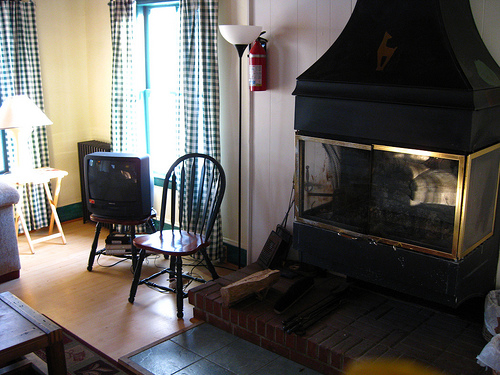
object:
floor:
[0, 216, 246, 363]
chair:
[127, 151, 226, 320]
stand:
[85, 209, 158, 272]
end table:
[0, 167, 68, 253]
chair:
[0, 186, 25, 284]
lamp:
[0, 94, 53, 182]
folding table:
[0, 167, 70, 255]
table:
[1, 290, 151, 374]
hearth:
[188, 230, 500, 374]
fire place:
[289, 0, 498, 321]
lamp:
[218, 25, 261, 267]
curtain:
[105, 2, 138, 155]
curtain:
[175, 4, 223, 263]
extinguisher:
[247, 30, 269, 91]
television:
[83, 152, 154, 218]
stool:
[84, 207, 158, 272]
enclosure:
[290, 129, 500, 266]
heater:
[77, 140, 111, 223]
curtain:
[1, 2, 53, 234]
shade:
[216, 23, 257, 45]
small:
[94, 169, 129, 202]